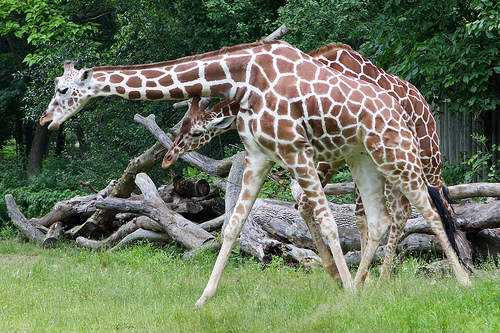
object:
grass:
[3, 227, 498, 332]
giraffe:
[164, 43, 477, 309]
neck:
[91, 39, 263, 102]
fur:
[295, 58, 314, 78]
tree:
[26, 5, 102, 181]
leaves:
[5, 1, 44, 18]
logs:
[92, 183, 204, 244]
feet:
[187, 287, 217, 312]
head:
[37, 57, 92, 132]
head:
[161, 90, 221, 171]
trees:
[439, 1, 499, 104]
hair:
[427, 183, 466, 259]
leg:
[193, 156, 272, 311]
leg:
[279, 148, 358, 294]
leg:
[342, 149, 393, 291]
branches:
[16, 22, 101, 66]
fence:
[417, 90, 498, 181]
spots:
[109, 71, 128, 84]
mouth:
[40, 119, 57, 131]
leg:
[370, 131, 472, 286]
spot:
[140, 65, 167, 81]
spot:
[204, 60, 228, 81]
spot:
[338, 47, 362, 74]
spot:
[415, 118, 429, 138]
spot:
[337, 104, 358, 128]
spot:
[295, 58, 320, 83]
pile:
[5, 192, 45, 238]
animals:
[37, 37, 479, 310]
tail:
[404, 112, 477, 270]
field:
[2, 139, 498, 332]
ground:
[4, 185, 498, 331]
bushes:
[5, 188, 57, 221]